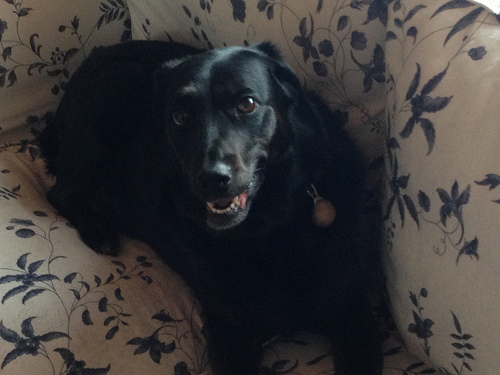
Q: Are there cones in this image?
A: No, there are no cones.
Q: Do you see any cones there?
A: No, there are no cones.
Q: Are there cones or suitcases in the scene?
A: No, there are no cones or suitcases.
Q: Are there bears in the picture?
A: No, there are no bears.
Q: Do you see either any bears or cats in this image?
A: No, there are no bears or cats.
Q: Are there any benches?
A: No, there are no benches.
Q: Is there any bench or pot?
A: No, there are no benches or pots.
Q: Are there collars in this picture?
A: Yes, there is a collar.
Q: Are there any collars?
A: Yes, there is a collar.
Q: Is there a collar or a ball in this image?
A: Yes, there is a collar.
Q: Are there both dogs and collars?
A: Yes, there are both a collar and a dog.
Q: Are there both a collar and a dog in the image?
A: Yes, there are both a collar and a dog.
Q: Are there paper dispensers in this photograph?
A: No, there are no paper dispensers.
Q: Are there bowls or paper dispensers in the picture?
A: No, there are no paper dispensers or bowls.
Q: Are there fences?
A: No, there are no fences.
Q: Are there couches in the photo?
A: Yes, there is a couch.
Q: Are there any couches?
A: Yes, there is a couch.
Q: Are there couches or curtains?
A: Yes, there is a couch.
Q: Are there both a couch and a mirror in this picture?
A: No, there is a couch but no mirrors.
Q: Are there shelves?
A: No, there are no shelves.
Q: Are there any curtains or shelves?
A: No, there are no shelves or curtains.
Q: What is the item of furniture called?
A: The piece of furniture is a couch.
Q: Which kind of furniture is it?
A: The piece of furniture is a couch.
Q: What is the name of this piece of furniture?
A: This is a couch.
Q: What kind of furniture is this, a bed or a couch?
A: This is a couch.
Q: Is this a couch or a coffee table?
A: This is a couch.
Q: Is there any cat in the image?
A: No, there are no cats.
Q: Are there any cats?
A: No, there are no cats.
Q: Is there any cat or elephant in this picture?
A: No, there are no cats or elephants.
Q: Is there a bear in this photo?
A: No, there are no bears.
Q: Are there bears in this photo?
A: No, there are no bears.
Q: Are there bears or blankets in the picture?
A: No, there are no bears or blankets.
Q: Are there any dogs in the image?
A: Yes, there is a dog.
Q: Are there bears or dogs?
A: Yes, there is a dog.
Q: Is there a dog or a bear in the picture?
A: Yes, there is a dog.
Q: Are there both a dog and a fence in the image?
A: No, there is a dog but no fences.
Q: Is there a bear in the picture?
A: No, there are no bears.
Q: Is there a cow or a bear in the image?
A: No, there are no bears or cows.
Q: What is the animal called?
A: The animal is a dog.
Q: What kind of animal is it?
A: The animal is a dog.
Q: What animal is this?
A: That is a dog.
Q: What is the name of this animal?
A: That is a dog.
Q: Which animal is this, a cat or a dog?
A: That is a dog.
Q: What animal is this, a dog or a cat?
A: That is a dog.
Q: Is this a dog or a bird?
A: This is a dog.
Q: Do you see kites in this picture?
A: No, there are no kites.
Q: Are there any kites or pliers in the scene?
A: No, there are no kites or pliers.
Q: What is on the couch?
A: The flower is on the couch.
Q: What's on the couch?
A: The flower is on the couch.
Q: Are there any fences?
A: No, there are no fences.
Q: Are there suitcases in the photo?
A: No, there are no suitcases.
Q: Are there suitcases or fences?
A: No, there are no suitcases or fences.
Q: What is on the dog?
A: The tag is on the dog.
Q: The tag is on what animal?
A: The tag is on the dog.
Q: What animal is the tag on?
A: The tag is on the dog.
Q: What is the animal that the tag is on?
A: The animal is a dog.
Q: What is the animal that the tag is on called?
A: The animal is a dog.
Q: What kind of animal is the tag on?
A: The tag is on the dog.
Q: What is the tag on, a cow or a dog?
A: The tag is on a dog.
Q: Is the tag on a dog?
A: Yes, the tag is on a dog.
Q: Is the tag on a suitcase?
A: No, the tag is on a dog.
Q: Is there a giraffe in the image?
A: No, there are no giraffes.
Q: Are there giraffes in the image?
A: No, there are no giraffes.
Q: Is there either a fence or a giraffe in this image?
A: No, there are no giraffes or fences.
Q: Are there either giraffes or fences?
A: No, there are no giraffes or fences.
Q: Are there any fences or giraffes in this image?
A: No, there are no giraffes or fences.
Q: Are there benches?
A: No, there are no benches.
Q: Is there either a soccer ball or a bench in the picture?
A: No, there are no benches or soccer balls.